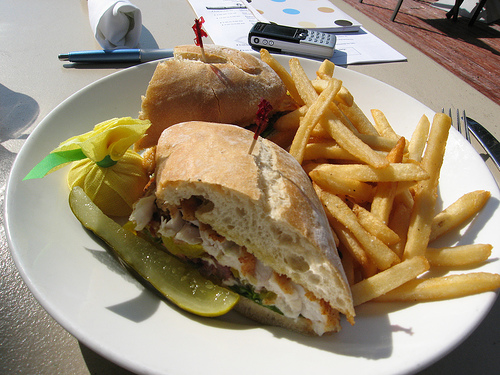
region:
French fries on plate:
[340, 92, 405, 254]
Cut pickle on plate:
[60, 176, 243, 321]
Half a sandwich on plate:
[140, 109, 378, 341]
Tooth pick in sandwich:
[235, 92, 279, 175]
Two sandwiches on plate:
[135, 21, 361, 343]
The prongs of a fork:
[436, 102, 471, 146]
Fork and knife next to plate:
[434, 102, 499, 168]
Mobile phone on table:
[242, 13, 346, 62]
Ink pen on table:
[48, 43, 166, 67]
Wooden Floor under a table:
[436, 37, 475, 55]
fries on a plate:
[302, 60, 496, 300]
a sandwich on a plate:
[151, 118, 332, 343]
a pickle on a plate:
[51, 180, 229, 335]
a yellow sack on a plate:
[72, 104, 142, 206]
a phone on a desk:
[247, 14, 337, 58]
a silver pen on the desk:
[62, 42, 187, 67]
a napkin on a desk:
[90, 0, 146, 42]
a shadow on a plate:
[335, 310, 410, 370]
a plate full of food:
[0, 44, 482, 365]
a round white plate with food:
[3, 49, 499, 372]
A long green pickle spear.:
[68, 176, 235, 319]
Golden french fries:
[248, 46, 498, 303]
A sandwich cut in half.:
[144, 37, 356, 339]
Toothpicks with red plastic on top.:
[193, 10, 275, 157]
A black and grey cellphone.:
[247, 18, 339, 61]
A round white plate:
[3, 53, 495, 373]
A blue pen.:
[56, 46, 176, 63]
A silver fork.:
[440, 105, 473, 145]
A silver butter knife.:
[462, 110, 498, 180]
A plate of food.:
[5, 26, 499, 373]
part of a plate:
[405, 342, 415, 352]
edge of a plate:
[261, 348, 273, 357]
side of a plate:
[388, 323, 401, 341]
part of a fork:
[454, 138, 456, 148]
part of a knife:
[463, 137, 473, 169]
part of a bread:
[286, 265, 311, 297]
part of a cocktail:
[169, 283, 188, 303]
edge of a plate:
[105, 292, 132, 313]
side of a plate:
[51, 295, 70, 324]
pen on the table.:
[60, 46, 151, 62]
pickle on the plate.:
[160, 274, 210, 310]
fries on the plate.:
[379, 206, 412, 243]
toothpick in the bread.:
[243, 127, 268, 150]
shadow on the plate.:
[117, 299, 154, 324]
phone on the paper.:
[253, 25, 328, 52]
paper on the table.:
[215, 12, 249, 44]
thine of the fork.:
[454, 105, 461, 129]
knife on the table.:
[471, 118, 497, 155]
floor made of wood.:
[447, 51, 488, 73]